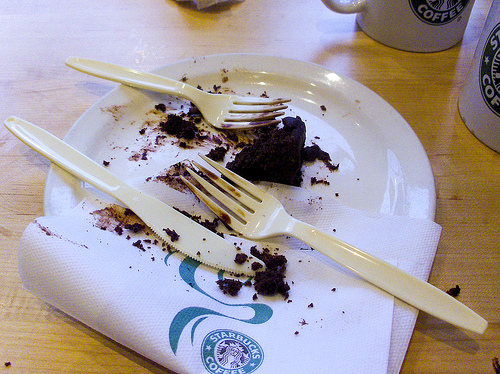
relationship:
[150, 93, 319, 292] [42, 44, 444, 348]
food on plate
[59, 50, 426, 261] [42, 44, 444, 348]
forks on plate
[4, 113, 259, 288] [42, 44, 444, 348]
knife on plate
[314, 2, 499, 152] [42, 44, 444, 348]
mug near plate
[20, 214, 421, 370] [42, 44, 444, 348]
napkin on plate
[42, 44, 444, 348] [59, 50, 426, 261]
plate with forks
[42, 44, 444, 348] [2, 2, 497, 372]
plate on table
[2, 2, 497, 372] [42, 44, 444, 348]
table under plate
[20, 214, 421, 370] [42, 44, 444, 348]
napkin on top of plate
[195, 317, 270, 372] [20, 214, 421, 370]
logo on napkin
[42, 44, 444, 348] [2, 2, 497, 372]
plate on top of table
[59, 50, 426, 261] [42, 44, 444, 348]
forks on top of plate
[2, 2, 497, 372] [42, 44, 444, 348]
untensils on plate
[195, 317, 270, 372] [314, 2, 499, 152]
logo on mug